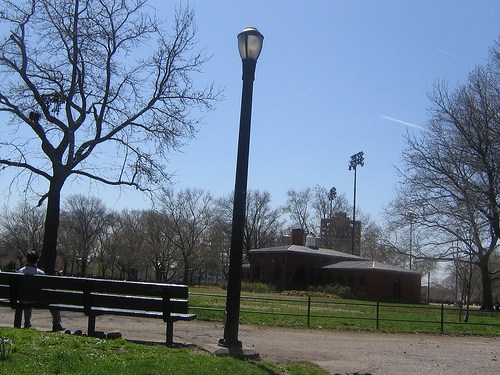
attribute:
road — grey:
[62, 327, 497, 373]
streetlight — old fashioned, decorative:
[213, 22, 270, 353]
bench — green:
[1, 265, 201, 347]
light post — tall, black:
[224, 19, 267, 355]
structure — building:
[242, 227, 423, 304]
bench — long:
[0, 271, 195, 325]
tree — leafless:
[368, 100, 484, 260]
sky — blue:
[293, 15, 419, 113]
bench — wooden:
[60, 266, 211, 336]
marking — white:
[380, 115, 437, 137]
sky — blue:
[3, 2, 492, 268]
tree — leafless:
[1, 2, 171, 274]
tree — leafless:
[373, 45, 498, 314]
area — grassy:
[0, 324, 325, 372]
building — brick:
[227, 242, 426, 302]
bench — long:
[0, 267, 197, 357]